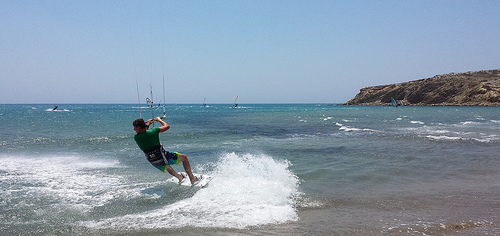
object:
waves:
[285, 110, 499, 144]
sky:
[0, 0, 500, 104]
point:
[344, 68, 500, 106]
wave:
[0, 147, 327, 236]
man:
[132, 116, 199, 185]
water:
[0, 103, 500, 236]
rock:
[342, 68, 500, 107]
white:
[195, 165, 207, 206]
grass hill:
[342, 68, 500, 108]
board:
[170, 171, 214, 189]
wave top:
[91, 150, 323, 234]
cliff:
[340, 68, 500, 107]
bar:
[144, 114, 166, 122]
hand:
[154, 116, 162, 122]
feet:
[177, 173, 199, 183]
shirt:
[134, 126, 163, 152]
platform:
[168, 171, 214, 189]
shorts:
[147, 151, 182, 173]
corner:
[344, 0, 499, 236]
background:
[0, 0, 500, 236]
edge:
[342, 87, 363, 104]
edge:
[272, 152, 302, 222]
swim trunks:
[145, 149, 181, 174]